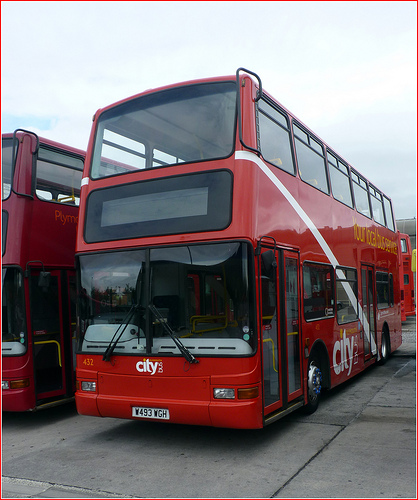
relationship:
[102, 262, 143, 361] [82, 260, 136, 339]
wiper on windshield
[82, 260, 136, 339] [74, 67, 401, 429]
windshield on bus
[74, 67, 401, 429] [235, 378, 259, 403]
bus has signal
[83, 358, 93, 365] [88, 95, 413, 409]
numbers are on bus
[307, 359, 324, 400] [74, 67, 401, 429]
rims on bus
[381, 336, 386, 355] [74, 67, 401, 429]
rims on bus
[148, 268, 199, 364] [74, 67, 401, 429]
wiper on bus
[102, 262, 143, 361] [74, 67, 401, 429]
wiper on bus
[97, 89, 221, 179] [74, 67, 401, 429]
window on bus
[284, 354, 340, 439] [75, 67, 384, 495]
tire on bus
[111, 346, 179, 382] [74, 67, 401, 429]
logo on front of bus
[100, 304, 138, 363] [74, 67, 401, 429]
blades on bus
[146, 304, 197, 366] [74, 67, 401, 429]
blades on bus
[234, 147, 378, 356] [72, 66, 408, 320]
stripe on bus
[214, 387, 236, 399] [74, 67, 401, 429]
headlight on bus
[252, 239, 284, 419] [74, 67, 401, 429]
door on bus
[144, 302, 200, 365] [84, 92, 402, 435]
wiper on bus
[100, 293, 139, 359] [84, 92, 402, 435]
wiper on bus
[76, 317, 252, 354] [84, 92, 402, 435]
dashboard on bus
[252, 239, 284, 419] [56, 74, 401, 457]
door on bus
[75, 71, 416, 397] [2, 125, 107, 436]
bus left of bus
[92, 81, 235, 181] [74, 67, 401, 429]
windshield on bus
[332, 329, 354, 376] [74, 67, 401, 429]
word on bus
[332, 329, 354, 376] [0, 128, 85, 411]
word on bus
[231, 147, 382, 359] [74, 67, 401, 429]
white line on bus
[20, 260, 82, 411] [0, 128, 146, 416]
doors on bus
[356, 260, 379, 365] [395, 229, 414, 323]
doors on bus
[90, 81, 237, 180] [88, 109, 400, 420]
window on bus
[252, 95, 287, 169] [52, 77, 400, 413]
window on bus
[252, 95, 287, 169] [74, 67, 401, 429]
window on bus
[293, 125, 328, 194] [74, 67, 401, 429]
window on bus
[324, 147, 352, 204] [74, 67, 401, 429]
window on bus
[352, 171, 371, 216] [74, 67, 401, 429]
window on bus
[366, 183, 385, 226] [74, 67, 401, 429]
window on bus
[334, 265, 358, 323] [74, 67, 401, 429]
window on bus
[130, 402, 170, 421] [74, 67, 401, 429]
license plate on bus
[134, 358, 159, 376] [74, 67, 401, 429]
word in front of bus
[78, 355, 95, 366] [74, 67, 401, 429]
numbers on bus